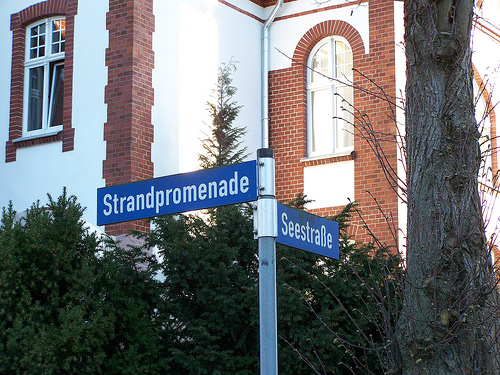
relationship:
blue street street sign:
[276, 200, 341, 260] [276, 202, 341, 262]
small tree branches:
[199, 55, 255, 169] [198, 55, 255, 169]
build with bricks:
[101, 0, 158, 237] [269, 20, 395, 256]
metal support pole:
[248, 147, 286, 375] [251, 146, 279, 374]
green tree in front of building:
[203, 50, 254, 246] [198, 55, 255, 169]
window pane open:
[43, 49, 66, 137] [43, 49, 66, 137]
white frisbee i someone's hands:
[53, 62, 66, 88] [52, 61, 66, 88]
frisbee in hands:
[58, 65, 66, 87] [55, 63, 66, 82]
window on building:
[28, 67, 43, 130] [4, 2, 494, 278]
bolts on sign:
[246, 158, 271, 242] [251, 197, 264, 242]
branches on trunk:
[285, 25, 425, 215] [380, 5, 472, 373]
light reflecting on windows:
[177, 7, 257, 211] [287, 8, 368, 220]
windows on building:
[287, 8, 368, 220] [0, 0, 500, 348]